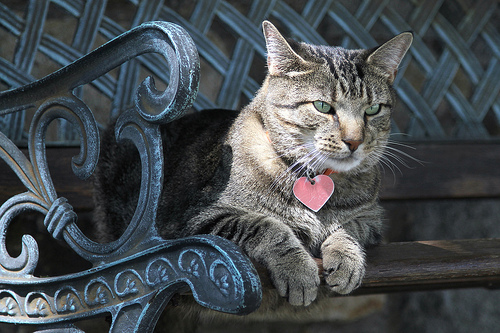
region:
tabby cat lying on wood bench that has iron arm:
[0, 18, 497, 332]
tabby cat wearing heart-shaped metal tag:
[94, 21, 413, 307]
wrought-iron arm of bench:
[0, 21, 266, 332]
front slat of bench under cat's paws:
[263, 237, 498, 298]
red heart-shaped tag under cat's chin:
[290, 170, 335, 210]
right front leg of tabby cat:
[201, 207, 322, 309]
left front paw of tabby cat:
[319, 232, 366, 296]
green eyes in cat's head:
[261, 17, 415, 176]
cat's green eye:
[311, 98, 338, 115]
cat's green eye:
[363, 99, 384, 117]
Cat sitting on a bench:
[26, 23, 400, 298]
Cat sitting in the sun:
[40, 39, 406, 303]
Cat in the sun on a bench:
[46, 30, 406, 302]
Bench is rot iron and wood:
[3, 106, 478, 310]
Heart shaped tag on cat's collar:
[276, 164, 346, 219]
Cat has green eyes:
[298, 91, 391, 127]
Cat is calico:
[172, 114, 315, 261]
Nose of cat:
[328, 126, 373, 152]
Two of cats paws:
[257, 226, 374, 318]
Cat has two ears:
[246, 16, 416, 87]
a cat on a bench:
[67, 16, 414, 316]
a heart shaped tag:
[291, 173, 336, 212]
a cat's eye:
[310, 97, 335, 113]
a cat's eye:
[364, 102, 382, 117]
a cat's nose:
[342, 138, 365, 152]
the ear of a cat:
[260, 18, 314, 75]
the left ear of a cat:
[370, 32, 412, 79]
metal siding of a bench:
[1, 18, 256, 332]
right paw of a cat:
[270, 257, 318, 307]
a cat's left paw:
[319, 253, 369, 295]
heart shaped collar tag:
[288, 171, 335, 214]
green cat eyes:
[306, 93, 388, 123]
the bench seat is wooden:
[169, 215, 498, 303]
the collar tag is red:
[289, 170, 336, 212]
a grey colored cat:
[81, 17, 428, 314]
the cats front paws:
[263, 245, 376, 313]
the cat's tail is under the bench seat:
[151, 268, 341, 324]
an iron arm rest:
[0, 18, 271, 325]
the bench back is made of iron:
[0, 0, 499, 150]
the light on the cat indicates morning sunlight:
[216, 17, 424, 304]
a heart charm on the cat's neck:
[288, 165, 335, 214]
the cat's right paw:
[253, 227, 323, 311]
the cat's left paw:
[318, 228, 368, 298]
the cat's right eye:
[310, 92, 338, 121]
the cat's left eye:
[360, 94, 386, 121]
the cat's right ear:
[253, 14, 320, 84]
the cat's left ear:
[358, 27, 416, 79]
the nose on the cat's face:
[338, 108, 368, 152]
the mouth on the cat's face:
[324, 146, 364, 167]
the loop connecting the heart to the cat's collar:
[300, 162, 322, 185]